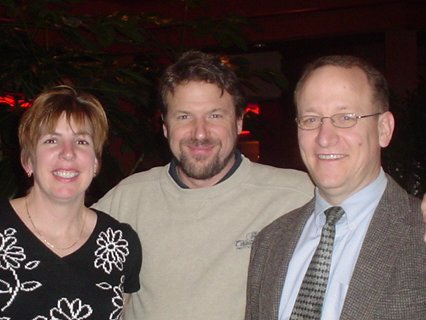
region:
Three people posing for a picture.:
[6, 27, 415, 313]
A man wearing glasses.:
[283, 47, 405, 212]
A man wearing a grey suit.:
[243, 59, 425, 318]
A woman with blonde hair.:
[6, 79, 117, 208]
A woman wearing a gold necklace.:
[0, 78, 113, 258]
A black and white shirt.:
[2, 187, 144, 318]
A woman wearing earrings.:
[2, 82, 111, 198]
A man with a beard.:
[150, 42, 254, 183]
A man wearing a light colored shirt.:
[95, 55, 307, 317]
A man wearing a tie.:
[272, 53, 378, 315]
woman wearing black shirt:
[3, 229, 87, 293]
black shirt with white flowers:
[36, 266, 82, 310]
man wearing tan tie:
[309, 230, 338, 304]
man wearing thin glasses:
[304, 92, 356, 151]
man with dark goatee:
[185, 153, 222, 179]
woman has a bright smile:
[47, 156, 73, 178]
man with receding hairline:
[307, 69, 364, 102]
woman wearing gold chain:
[30, 204, 73, 261]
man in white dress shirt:
[339, 218, 355, 250]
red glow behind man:
[240, 89, 264, 142]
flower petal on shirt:
[94, 227, 108, 242]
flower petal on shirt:
[104, 225, 111, 240]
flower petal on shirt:
[112, 229, 121, 241]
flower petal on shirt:
[114, 238, 129, 247]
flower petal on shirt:
[118, 243, 129, 257]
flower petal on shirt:
[115, 250, 125, 265]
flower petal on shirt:
[96, 234, 103, 246]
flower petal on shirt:
[2, 234, 16, 250]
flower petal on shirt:
[4, 246, 24, 253]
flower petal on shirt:
[4, 253, 19, 270]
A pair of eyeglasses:
[293, 105, 390, 135]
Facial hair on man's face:
[168, 135, 232, 185]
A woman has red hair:
[13, 78, 111, 207]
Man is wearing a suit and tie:
[242, 51, 424, 317]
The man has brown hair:
[149, 42, 253, 183]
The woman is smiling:
[8, 77, 114, 208]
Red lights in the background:
[0, 86, 263, 141]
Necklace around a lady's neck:
[19, 190, 92, 254]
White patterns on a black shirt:
[1, 196, 144, 317]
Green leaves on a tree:
[1, 2, 289, 198]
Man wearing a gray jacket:
[242, 62, 425, 318]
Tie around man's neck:
[292, 204, 348, 318]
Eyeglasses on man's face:
[295, 105, 367, 139]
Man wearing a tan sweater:
[95, 49, 316, 318]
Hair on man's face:
[172, 147, 234, 181]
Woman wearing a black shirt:
[1, 87, 144, 318]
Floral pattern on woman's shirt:
[2, 203, 131, 318]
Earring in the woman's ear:
[23, 166, 38, 178]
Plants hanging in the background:
[1, 0, 291, 175]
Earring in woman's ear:
[84, 166, 99, 182]